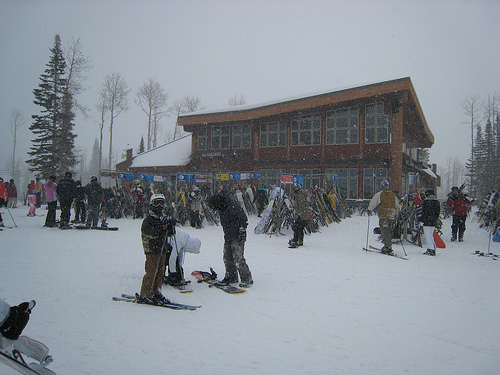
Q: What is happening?
A: Skiing.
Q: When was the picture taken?
A: Daytime.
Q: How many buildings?
A: One.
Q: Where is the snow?
A: On the ground.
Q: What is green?
A: Trees.